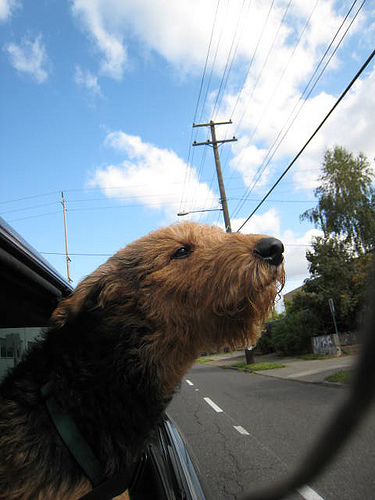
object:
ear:
[50, 263, 117, 334]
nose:
[252, 234, 285, 259]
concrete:
[163, 349, 374, 498]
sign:
[327, 298, 335, 314]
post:
[209, 119, 256, 364]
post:
[60, 191, 71, 287]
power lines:
[37, 249, 115, 257]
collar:
[38, 376, 108, 486]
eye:
[169, 243, 191, 262]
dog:
[0, 220, 289, 498]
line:
[185, 379, 194, 386]